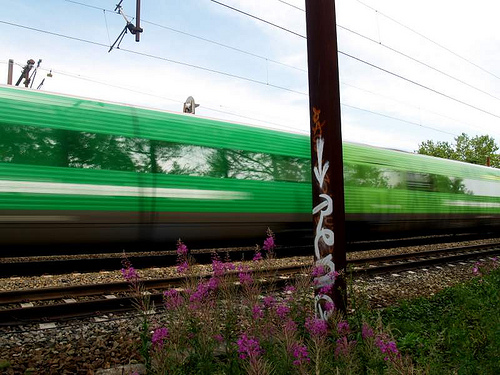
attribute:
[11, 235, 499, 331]
tracks — train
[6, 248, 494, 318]
tracks — train, brown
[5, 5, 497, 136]
lines — power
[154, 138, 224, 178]
window — glass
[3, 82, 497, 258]
train — passenger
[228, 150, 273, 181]
window — glass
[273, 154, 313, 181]
window — glass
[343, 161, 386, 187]
window — glass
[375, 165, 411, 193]
window — glass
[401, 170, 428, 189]
window — glass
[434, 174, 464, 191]
window — glass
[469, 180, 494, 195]
window — glass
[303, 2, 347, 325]
pole — brown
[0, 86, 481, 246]
train — passenger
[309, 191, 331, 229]
letter — white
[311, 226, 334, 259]
letter — white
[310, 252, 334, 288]
letter — white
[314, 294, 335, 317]
letter — white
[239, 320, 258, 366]
flower — pink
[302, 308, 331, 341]
flower — pink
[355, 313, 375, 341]
flower — pink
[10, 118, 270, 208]
train — green